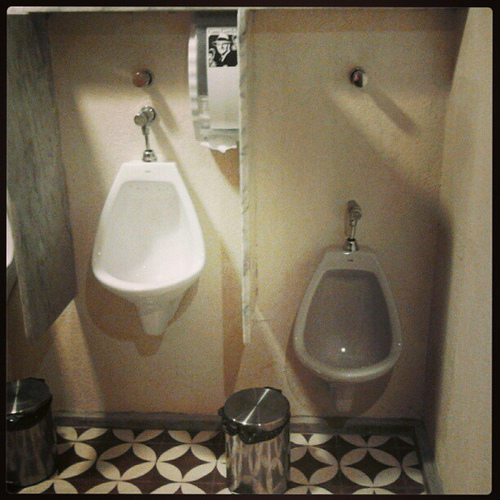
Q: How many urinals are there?
A: Two.